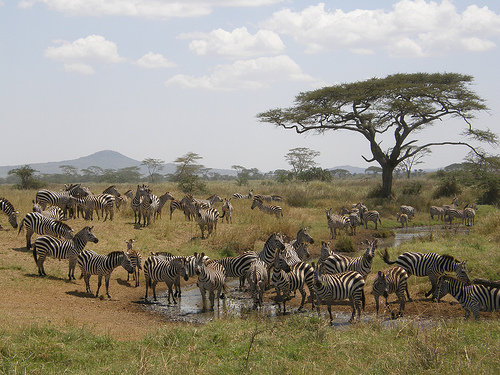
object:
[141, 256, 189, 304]
zebra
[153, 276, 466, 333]
river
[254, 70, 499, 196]
tree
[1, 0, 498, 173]
sky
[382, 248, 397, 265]
tail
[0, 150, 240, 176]
mountain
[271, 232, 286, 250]
head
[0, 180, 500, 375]
plain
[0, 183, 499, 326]
herd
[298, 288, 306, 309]
leg